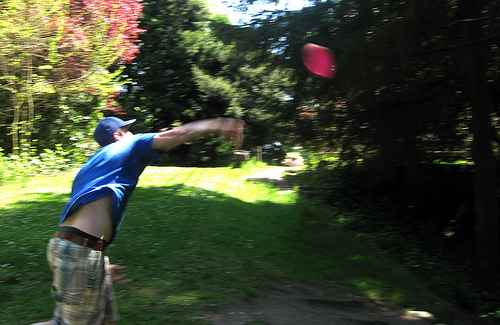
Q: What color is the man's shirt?
A: Blue.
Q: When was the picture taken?
A: During the day.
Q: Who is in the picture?
A: A man.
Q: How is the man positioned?
A: He is leaning.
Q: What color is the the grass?
A: Green.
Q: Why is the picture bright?
A: The sun is out.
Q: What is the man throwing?
A: A water balloon.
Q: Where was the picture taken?
A: In a park.